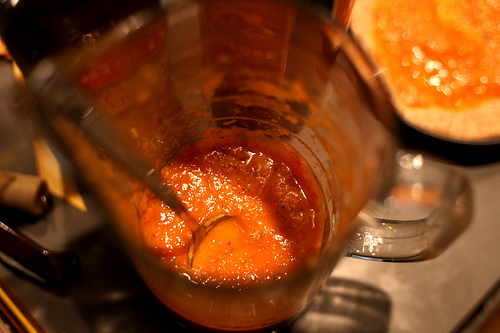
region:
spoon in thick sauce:
[40, 18, 485, 318]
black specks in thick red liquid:
[130, 145, 325, 297]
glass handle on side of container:
[345, 140, 480, 276]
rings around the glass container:
[130, 85, 345, 230]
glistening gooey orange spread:
[365, 5, 495, 132]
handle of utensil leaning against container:
[41, 67, 201, 232]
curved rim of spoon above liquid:
[185, 205, 235, 265]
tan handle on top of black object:
[5, 160, 115, 310]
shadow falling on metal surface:
[295, 271, 445, 326]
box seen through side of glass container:
[165, 0, 335, 95]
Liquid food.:
[142, 142, 329, 268]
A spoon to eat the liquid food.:
[41, 66, 254, 255]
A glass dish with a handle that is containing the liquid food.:
[90, 0, 465, 331]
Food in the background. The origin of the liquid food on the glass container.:
[362, 0, 498, 133]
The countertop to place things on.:
[297, 185, 499, 332]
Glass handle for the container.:
[389, 154, 495, 263]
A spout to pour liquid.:
[27, 40, 93, 129]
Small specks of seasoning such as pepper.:
[210, 144, 304, 222]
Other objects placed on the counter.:
[5, 159, 97, 287]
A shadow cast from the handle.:
[310, 253, 382, 331]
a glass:
[53, 17, 401, 327]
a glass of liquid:
[55, 9, 401, 331]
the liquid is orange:
[68, 11, 375, 313]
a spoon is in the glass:
[27, 21, 407, 302]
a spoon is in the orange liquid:
[34, 8, 403, 301]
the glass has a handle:
[49, 5, 496, 282]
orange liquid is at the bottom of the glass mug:
[43, 6, 480, 293]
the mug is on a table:
[45, 11, 484, 331]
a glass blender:
[54, 15, 479, 323]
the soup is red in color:
[175, 170, 302, 273]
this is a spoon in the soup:
[159, 196, 239, 258]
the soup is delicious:
[204, 163, 281, 278]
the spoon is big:
[145, 178, 204, 262]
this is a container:
[164, 60, 306, 140]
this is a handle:
[364, 179, 472, 262]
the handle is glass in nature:
[349, 173, 464, 259]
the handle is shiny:
[370, 177, 470, 257]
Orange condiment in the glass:
[141, 121, 330, 285]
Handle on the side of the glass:
[348, 157, 473, 262]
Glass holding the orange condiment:
[17, 1, 477, 330]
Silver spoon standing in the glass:
[38, 66, 248, 272]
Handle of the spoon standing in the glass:
[26, 59, 196, 231]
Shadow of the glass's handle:
[311, 274, 392, 331]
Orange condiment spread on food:
[371, 0, 498, 108]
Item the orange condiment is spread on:
[351, 4, 499, 143]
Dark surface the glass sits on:
[2, 153, 499, 331]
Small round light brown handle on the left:
[0, 170, 53, 216]